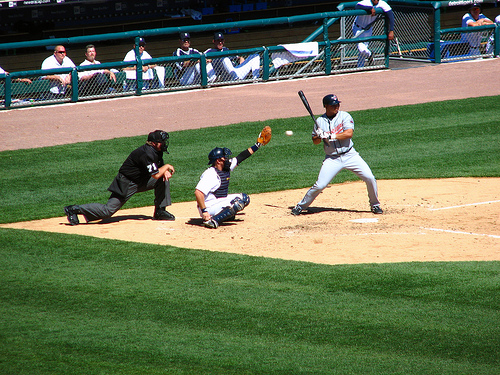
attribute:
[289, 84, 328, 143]
black bat — black 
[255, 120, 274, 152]
brown catcher's mitt — brown , held out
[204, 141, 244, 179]
black catcher's mask — black 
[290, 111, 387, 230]
light grey uniform — light grey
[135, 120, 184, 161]
black mask — black 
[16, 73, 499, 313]
field is green — green 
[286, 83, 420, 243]
grey outfit — grey 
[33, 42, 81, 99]
shirts are white — white 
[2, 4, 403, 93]
fence is dull blue — blue 